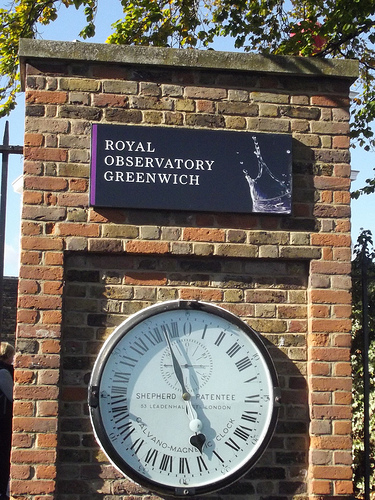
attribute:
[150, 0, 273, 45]
branches — hanging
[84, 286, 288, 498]
border — black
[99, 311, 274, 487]
face — white